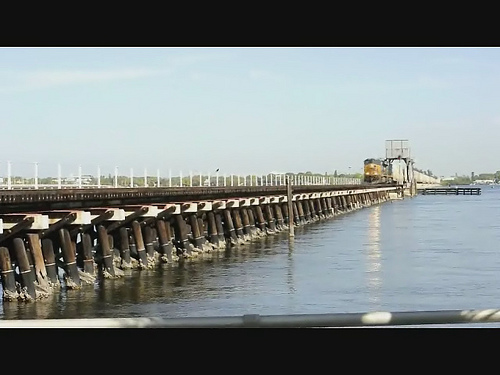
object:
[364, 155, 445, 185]
train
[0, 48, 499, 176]
sky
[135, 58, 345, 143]
sky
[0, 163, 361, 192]
pylons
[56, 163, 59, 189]
white pole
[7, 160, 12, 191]
white pole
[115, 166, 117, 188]
white pole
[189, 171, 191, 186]
white pole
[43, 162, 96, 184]
building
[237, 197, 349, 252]
ground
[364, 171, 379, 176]
headlights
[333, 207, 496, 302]
water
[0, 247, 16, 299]
rail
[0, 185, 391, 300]
rail bridge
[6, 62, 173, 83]
thin cloud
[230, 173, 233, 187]
white fence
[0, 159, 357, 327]
pier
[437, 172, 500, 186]
landscape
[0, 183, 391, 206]
tracks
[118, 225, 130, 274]
support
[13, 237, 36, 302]
support